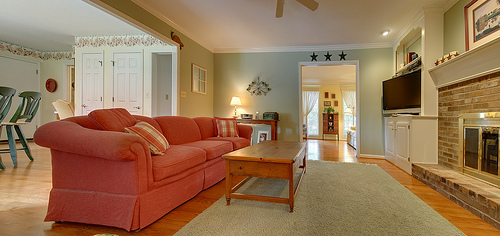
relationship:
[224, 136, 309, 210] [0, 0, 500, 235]
table in living room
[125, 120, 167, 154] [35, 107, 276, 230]
pillow on sofa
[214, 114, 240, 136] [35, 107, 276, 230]
pillow on sofa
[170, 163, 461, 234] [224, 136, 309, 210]
rug under table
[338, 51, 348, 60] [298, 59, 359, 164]
star above door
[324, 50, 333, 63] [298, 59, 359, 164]
star above door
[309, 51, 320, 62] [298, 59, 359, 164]
star above door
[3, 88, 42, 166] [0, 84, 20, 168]
chair near a chair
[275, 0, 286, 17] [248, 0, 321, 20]
blade of a fan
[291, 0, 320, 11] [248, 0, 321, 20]
blade of a fan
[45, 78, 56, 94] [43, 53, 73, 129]
plate on a wall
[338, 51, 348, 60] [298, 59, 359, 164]
star above a door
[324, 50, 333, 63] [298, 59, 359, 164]
star above a door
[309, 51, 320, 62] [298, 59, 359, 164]
star above a door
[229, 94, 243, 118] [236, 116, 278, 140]
lamp on table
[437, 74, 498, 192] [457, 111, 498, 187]
fireplace has a door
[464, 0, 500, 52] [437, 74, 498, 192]
picture above fireplace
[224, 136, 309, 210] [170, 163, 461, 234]
table on rug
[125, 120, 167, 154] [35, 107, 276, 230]
pillow on a sofa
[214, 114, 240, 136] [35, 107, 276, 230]
pillow on a sofa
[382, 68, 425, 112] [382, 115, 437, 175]
television on cabinet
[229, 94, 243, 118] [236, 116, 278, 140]
lamp on a table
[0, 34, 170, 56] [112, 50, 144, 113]
wallpaper above door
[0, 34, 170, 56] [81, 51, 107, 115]
wallpaper above door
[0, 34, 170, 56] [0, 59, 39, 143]
wallpaper above door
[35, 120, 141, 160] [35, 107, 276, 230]
arm of sofa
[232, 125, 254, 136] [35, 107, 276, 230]
arm of sofa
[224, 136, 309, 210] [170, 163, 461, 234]
table on a rug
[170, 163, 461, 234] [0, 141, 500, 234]
rug on floor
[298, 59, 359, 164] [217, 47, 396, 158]
door on a wall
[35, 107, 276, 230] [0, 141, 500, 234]
sofa on floor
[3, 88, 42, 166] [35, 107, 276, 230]
chair behind a sofa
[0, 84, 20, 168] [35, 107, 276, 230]
chair behind a sofa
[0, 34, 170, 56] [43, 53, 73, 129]
wallpaper on wall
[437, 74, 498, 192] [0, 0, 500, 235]
fireplace in a living room